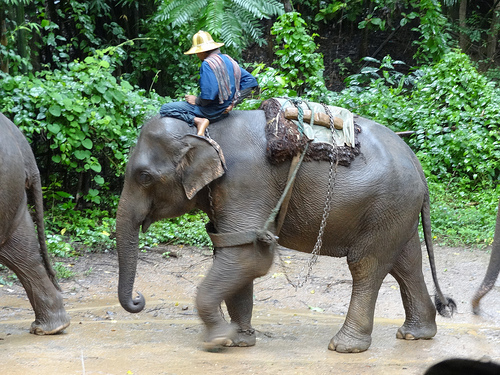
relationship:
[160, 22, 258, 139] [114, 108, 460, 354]
man on elephant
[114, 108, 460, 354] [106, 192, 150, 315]
elephant has trunk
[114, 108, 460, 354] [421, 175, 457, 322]
elephant has tail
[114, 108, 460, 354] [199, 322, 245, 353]
elephant has paw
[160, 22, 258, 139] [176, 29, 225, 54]
person wearing hat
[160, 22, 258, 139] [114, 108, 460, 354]
person on elephant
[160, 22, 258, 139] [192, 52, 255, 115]
man has shirt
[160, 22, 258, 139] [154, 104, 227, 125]
man has pants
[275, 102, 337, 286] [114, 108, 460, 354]
chain on elephant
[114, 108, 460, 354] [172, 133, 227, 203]
elephant has ear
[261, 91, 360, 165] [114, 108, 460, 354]
blanket on elephant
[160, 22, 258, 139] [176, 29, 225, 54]
man has hat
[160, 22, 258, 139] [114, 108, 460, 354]
man riding elephant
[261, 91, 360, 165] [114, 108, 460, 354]
load on elephant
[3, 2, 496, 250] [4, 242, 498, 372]
bushes along pathway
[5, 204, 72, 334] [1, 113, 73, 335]
leg of elephant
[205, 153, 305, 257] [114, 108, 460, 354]
harness on elephant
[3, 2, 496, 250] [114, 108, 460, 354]
forest behind elephant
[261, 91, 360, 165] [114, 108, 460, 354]
saddle on elephant